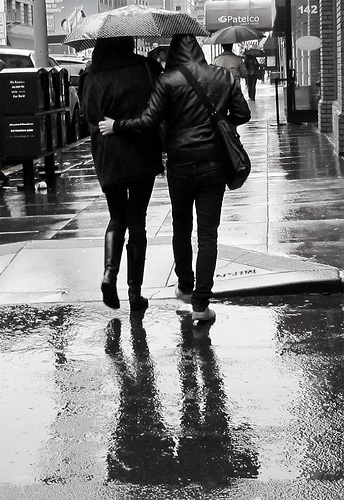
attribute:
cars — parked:
[0, 47, 91, 143]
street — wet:
[9, 293, 339, 370]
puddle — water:
[2, 311, 69, 412]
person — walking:
[70, 37, 173, 316]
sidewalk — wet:
[0, 79, 343, 303]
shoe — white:
[190, 307, 218, 320]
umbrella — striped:
[69, 6, 249, 51]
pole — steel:
[31, 0, 48, 70]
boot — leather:
[67, 196, 126, 306]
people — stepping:
[84, 29, 245, 329]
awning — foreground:
[201, 0, 278, 30]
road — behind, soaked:
[280, 183, 326, 227]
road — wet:
[4, 305, 342, 499]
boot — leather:
[125, 226, 150, 311]